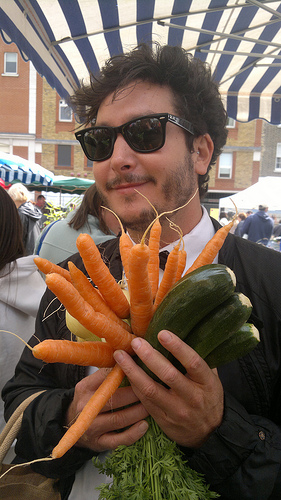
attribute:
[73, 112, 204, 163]
sunglasses — large, black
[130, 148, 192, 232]
beard — brown, patchy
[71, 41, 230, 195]
hair — brown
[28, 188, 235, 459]
carrots — orange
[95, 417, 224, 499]
heads — green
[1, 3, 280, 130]
canopy — white, blue, striped, green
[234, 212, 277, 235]
sweater — blue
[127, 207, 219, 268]
shirt — white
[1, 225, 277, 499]
jacket — black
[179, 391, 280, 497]
sleeve — black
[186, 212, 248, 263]
carrot — orange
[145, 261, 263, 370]
zucchinis — green, zucchini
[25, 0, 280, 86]
frame — metal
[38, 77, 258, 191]
wall — brick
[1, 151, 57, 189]
umbrella — striped, blue, white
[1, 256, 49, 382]
sweatshirt — white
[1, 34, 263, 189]
building — red, beige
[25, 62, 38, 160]
border — stone